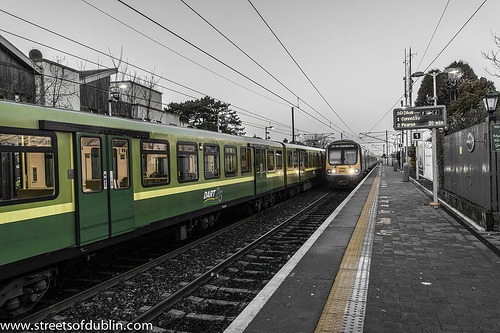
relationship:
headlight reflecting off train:
[349, 168, 355, 173] [320, 132, 384, 184]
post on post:
[392, 105, 447, 131] [411, 63, 468, 208]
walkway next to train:
[225, 158, 499, 331] [323, 139, 384, 184]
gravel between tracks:
[24, 184, 327, 328] [3, 182, 317, 327]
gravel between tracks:
[24, 184, 327, 328] [126, 180, 363, 327]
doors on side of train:
[72, 126, 138, 248] [0, 95, 325, 317]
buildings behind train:
[0, 26, 219, 129] [3, 91, 326, 284]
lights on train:
[7, 135, 293, 200] [3, 91, 326, 284]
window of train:
[141, 138, 173, 185] [1, 101, 293, 248]